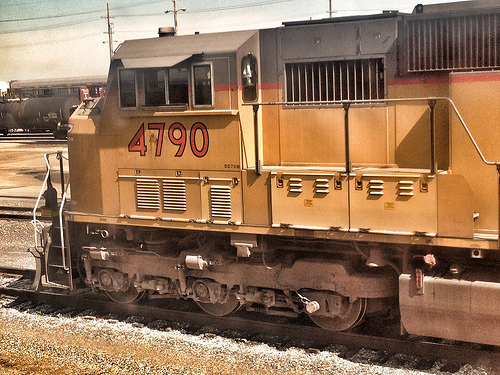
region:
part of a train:
[380, 262, 400, 280]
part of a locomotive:
[168, 258, 182, 288]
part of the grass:
[215, 340, 225, 350]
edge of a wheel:
[298, 270, 312, 288]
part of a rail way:
[218, 323, 244, 341]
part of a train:
[274, 264, 290, 286]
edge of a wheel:
[204, 300, 220, 314]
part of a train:
[164, 268, 184, 301]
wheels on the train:
[163, 252, 370, 333]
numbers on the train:
[115, 117, 220, 165]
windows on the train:
[126, 71, 211, 106]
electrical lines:
[18, 11, 79, 48]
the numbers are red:
[127, 123, 224, 166]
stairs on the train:
[35, 231, 70, 284]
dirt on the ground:
[80, 318, 168, 369]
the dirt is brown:
[86, 324, 144, 374]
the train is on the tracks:
[83, 293, 215, 325]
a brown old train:
[40, 16, 494, 361]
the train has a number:
[111, 121, 226, 177]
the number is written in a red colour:
[118, 123, 235, 161]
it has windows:
[107, 60, 232, 105]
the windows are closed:
[83, 57, 262, 124]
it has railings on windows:
[260, 61, 416, 121]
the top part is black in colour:
[101, 0, 499, 81]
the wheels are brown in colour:
[90, 235, 401, 340]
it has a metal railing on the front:
[23, 141, 75, 291]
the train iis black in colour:
[1, 65, 71, 128]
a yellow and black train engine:
[38, 1, 498, 351]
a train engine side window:
[114, 64, 213, 111]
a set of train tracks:
[0, 261, 499, 368]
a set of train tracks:
[0, 202, 42, 222]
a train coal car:
[0, 93, 77, 136]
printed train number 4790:
[124, 120, 212, 159]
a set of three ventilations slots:
[288, 177, 304, 194]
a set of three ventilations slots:
[316, 176, 328, 193]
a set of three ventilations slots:
[364, 179, 386, 199]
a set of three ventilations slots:
[397, 179, 414, 198]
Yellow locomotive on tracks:
[38, 70, 479, 348]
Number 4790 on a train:
[107, 98, 324, 246]